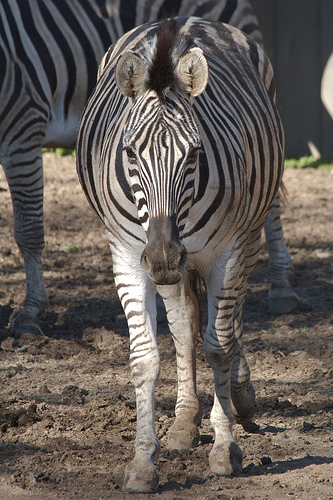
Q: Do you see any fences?
A: Yes, there is a fence.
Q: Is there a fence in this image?
A: Yes, there is a fence.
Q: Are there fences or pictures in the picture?
A: Yes, there is a fence.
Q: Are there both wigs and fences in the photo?
A: No, there is a fence but no wigs.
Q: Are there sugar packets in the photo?
A: No, there are no sugar packets.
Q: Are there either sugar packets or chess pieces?
A: No, there are no sugar packets or chess pieces.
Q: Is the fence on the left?
A: No, the fence is on the right of the image.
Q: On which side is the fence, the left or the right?
A: The fence is on the right of the image.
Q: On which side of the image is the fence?
A: The fence is on the right of the image.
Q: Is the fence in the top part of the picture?
A: Yes, the fence is in the top of the image.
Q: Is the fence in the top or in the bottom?
A: The fence is in the top of the image.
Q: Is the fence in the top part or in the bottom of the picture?
A: The fence is in the top of the image.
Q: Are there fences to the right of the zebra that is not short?
A: Yes, there is a fence to the right of the zebra.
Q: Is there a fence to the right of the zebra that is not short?
A: Yes, there is a fence to the right of the zebra.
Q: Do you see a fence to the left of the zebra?
A: No, the fence is to the right of the zebra.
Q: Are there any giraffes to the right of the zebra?
A: No, there is a fence to the right of the zebra.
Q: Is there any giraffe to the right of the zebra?
A: No, there is a fence to the right of the zebra.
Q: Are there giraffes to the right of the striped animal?
A: No, there is a fence to the right of the zebra.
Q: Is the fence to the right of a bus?
A: No, the fence is to the right of a zebra.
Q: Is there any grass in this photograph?
A: Yes, there is grass.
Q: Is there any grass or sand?
A: Yes, there is grass.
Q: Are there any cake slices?
A: No, there are no cake slices.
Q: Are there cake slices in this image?
A: No, there are no cake slices.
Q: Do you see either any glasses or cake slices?
A: No, there are no cake slices or glasses.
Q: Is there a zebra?
A: Yes, there is a zebra.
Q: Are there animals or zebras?
A: Yes, there is a zebra.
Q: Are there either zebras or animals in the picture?
A: Yes, there is a zebra.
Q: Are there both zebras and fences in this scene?
A: Yes, there are both a zebra and a fence.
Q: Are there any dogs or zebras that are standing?
A: Yes, the zebra is standing.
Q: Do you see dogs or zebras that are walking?
A: Yes, the zebra is walking.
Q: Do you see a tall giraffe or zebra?
A: Yes, there is a tall zebra.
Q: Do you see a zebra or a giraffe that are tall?
A: Yes, the zebra is tall.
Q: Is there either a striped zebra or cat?
A: Yes, there is a striped zebra.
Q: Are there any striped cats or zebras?
A: Yes, there is a striped zebra.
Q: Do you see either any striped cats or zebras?
A: Yes, there is a striped zebra.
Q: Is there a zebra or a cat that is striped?
A: Yes, the zebra is striped.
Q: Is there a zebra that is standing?
A: Yes, there is a zebra that is standing.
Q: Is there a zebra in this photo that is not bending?
A: Yes, there is a zebra that is standing.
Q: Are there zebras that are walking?
A: Yes, there is a zebra that is walking.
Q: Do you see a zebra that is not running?
A: Yes, there is a zebra that is walking .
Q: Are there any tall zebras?
A: Yes, there is a tall zebra.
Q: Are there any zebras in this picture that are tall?
A: Yes, there is a zebra that is tall.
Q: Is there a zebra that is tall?
A: Yes, there is a zebra that is tall.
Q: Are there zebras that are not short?
A: Yes, there is a tall zebra.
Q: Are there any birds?
A: No, there are no birds.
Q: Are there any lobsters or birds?
A: No, there are no birds or lobsters.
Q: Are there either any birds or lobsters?
A: No, there are no birds or lobsters.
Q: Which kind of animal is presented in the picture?
A: The animal is a zebra.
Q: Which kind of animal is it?
A: The animal is a zebra.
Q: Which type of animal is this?
A: That is a zebra.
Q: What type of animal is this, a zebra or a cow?
A: That is a zebra.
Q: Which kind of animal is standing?
A: The animal is a zebra.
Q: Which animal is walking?
A: The animal is a zebra.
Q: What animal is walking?
A: The animal is a zebra.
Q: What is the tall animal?
A: The animal is a zebra.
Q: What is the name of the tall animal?
A: The animal is a zebra.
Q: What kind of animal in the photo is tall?
A: The animal is a zebra.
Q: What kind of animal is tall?
A: The animal is a zebra.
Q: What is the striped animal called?
A: The animal is a zebra.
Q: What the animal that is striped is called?
A: The animal is a zebra.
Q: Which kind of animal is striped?
A: The animal is a zebra.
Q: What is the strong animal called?
A: The animal is a zebra.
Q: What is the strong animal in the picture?
A: The animal is a zebra.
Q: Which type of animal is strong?
A: The animal is a zebra.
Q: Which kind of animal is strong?
A: The animal is a zebra.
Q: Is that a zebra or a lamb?
A: That is a zebra.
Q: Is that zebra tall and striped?
A: Yes, the zebra is tall and striped.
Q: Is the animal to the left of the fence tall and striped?
A: Yes, the zebra is tall and striped.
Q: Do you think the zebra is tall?
A: Yes, the zebra is tall.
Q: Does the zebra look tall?
A: Yes, the zebra is tall.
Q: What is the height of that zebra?
A: The zebra is tall.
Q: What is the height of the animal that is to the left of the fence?
A: The zebra is tall.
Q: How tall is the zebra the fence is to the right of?
A: The zebra is tall.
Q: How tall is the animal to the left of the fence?
A: The zebra is tall.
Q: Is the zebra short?
A: No, the zebra is tall.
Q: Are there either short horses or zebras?
A: No, there is a zebra but it is tall.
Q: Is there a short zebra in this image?
A: No, there is a zebra but it is tall.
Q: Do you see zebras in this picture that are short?
A: No, there is a zebra but it is tall.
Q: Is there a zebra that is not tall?
A: No, there is a zebra but it is tall.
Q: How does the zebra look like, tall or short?
A: The zebra is tall.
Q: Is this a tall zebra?
A: Yes, this is a tall zebra.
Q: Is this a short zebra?
A: No, this is a tall zebra.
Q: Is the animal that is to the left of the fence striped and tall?
A: Yes, the zebra is striped and tall.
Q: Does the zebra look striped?
A: Yes, the zebra is striped.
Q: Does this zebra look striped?
A: Yes, the zebra is striped.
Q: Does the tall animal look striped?
A: Yes, the zebra is striped.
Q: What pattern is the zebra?
A: The zebra is striped.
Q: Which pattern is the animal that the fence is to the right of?
A: The zebra is striped.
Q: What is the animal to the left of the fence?
A: The animal is a zebra.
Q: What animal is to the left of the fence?
A: The animal is a zebra.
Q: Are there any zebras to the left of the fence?
A: Yes, there is a zebra to the left of the fence.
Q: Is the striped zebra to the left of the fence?
A: Yes, the zebra is to the left of the fence.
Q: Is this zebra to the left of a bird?
A: No, the zebra is to the left of the fence.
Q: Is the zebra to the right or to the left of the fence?
A: The zebra is to the left of the fence.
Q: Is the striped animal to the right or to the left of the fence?
A: The zebra is to the left of the fence.